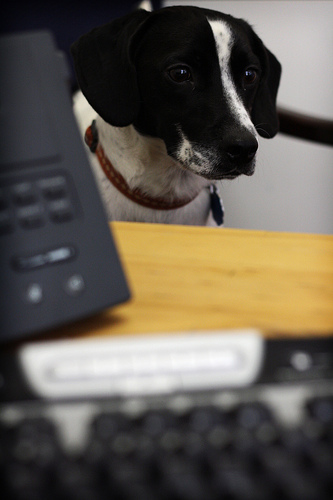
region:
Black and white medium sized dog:
[69, 5, 280, 226]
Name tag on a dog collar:
[209, 183, 224, 226]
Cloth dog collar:
[83, 120, 210, 210]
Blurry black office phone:
[1, 29, 129, 340]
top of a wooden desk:
[8, 219, 332, 355]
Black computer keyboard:
[1, 328, 332, 498]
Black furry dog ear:
[67, 8, 151, 127]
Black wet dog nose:
[217, 126, 258, 167]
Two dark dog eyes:
[165, 63, 260, 85]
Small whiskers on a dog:
[156, 120, 269, 178]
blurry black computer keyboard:
[0, 342, 332, 498]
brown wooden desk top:
[178, 256, 307, 320]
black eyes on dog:
[159, 51, 265, 95]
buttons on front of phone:
[0, 153, 86, 315]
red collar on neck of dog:
[79, 121, 202, 214]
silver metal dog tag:
[202, 183, 233, 228]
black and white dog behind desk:
[62, 14, 302, 249]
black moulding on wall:
[279, 104, 332, 155]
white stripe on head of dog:
[207, 19, 259, 148]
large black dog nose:
[210, 127, 272, 175]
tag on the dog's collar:
[204, 185, 225, 228]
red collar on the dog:
[108, 168, 195, 212]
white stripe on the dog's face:
[212, 20, 255, 145]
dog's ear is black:
[71, 9, 147, 127]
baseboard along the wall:
[282, 105, 325, 151]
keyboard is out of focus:
[20, 395, 308, 492]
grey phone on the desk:
[7, 30, 139, 332]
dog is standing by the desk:
[66, 9, 296, 214]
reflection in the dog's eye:
[177, 64, 186, 74]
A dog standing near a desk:
[82, 10, 295, 209]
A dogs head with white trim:
[68, 1, 281, 168]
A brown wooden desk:
[154, 245, 268, 303]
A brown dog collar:
[87, 132, 191, 214]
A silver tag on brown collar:
[202, 182, 237, 221]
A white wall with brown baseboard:
[274, 17, 331, 86]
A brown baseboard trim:
[280, 103, 321, 168]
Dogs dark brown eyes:
[159, 60, 263, 93]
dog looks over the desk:
[65, 2, 284, 227]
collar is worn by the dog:
[83, 122, 225, 224]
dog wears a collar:
[70, 4, 285, 228]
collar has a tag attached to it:
[84, 120, 224, 225]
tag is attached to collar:
[201, 182, 227, 227]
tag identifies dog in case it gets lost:
[204, 184, 226, 224]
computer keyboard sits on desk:
[2, 334, 332, 499]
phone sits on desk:
[0, 26, 134, 337]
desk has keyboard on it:
[0, 219, 332, 497]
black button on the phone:
[44, 194, 74, 222]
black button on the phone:
[3, 176, 40, 203]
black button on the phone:
[10, 197, 48, 234]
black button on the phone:
[13, 248, 48, 276]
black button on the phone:
[63, 272, 83, 296]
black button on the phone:
[25, 280, 45, 305]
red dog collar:
[84, 128, 231, 215]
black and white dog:
[53, 8, 290, 226]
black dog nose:
[218, 124, 258, 163]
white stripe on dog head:
[204, 18, 262, 155]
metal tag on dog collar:
[207, 185, 237, 230]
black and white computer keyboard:
[1, 338, 328, 498]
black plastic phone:
[1, 32, 127, 346]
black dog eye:
[171, 59, 196, 85]